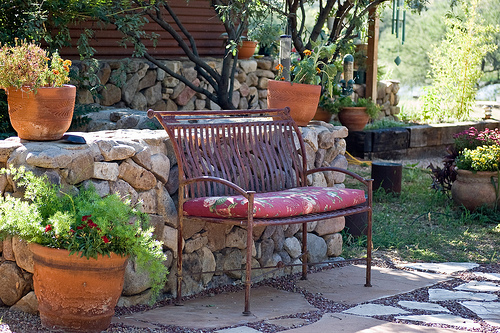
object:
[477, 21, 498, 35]
leaves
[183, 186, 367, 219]
cushion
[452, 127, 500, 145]
flowers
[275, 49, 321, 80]
flowers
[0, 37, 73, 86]
flowers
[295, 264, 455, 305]
flat stone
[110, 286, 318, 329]
flat stone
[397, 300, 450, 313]
flat stone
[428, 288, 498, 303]
flat stone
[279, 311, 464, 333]
flat stone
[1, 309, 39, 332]
small stones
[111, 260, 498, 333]
small stones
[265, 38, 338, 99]
plant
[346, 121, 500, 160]
wooden fence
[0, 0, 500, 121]
tree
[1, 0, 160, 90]
leaves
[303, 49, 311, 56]
flower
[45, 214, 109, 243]
flowers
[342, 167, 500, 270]
grass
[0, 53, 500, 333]
yard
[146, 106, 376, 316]
bench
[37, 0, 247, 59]
brown siding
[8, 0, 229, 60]
house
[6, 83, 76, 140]
flowerpot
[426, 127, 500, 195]
plant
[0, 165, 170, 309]
flowering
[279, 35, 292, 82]
birdfeeder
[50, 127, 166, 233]
gravel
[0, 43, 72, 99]
greenery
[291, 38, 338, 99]
greenery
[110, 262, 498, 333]
stone walkway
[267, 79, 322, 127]
feeders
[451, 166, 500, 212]
planter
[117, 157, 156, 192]
stone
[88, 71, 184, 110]
wall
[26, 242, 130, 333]
planter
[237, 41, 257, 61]
flower pot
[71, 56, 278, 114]
rock wall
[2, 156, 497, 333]
ground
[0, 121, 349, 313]
fence